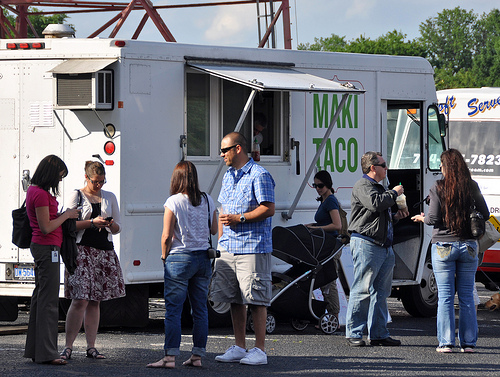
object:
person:
[144, 159, 218, 368]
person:
[57, 157, 127, 364]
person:
[24, 153, 70, 364]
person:
[407, 148, 492, 354]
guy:
[343, 150, 409, 345]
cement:
[0, 279, 500, 377]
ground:
[0, 281, 500, 377]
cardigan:
[68, 189, 124, 245]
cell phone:
[103, 216, 113, 223]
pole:
[109, 0, 138, 39]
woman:
[312, 170, 345, 331]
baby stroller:
[245, 223, 350, 333]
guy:
[211, 131, 276, 364]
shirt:
[216, 156, 274, 256]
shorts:
[209, 250, 272, 307]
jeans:
[429, 241, 479, 347]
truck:
[0, 25, 446, 328]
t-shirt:
[312, 190, 345, 241]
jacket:
[346, 176, 400, 247]